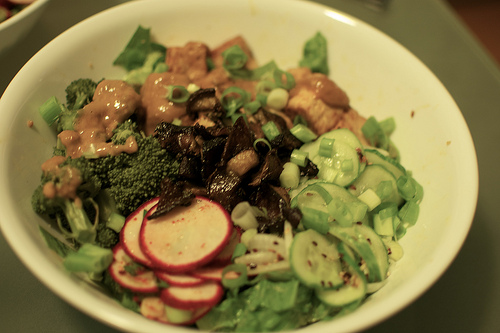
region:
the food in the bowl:
[30, 24, 423, 331]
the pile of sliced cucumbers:
[287, 129, 405, 306]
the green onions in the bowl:
[40, 24, 422, 331]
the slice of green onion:
[167, 84, 188, 104]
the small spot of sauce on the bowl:
[26, 119, 33, 128]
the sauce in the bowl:
[42, 37, 349, 208]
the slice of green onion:
[220, 264, 247, 285]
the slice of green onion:
[40, 97, 65, 127]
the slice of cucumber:
[289, 229, 345, 290]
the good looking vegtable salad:
[72, 88, 144, 149]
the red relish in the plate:
[127, 220, 237, 305]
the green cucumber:
[295, 185, 405, 265]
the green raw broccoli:
[90, 142, 176, 189]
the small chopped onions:
[265, 130, 360, 195]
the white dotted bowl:
[0, 61, 39, 205]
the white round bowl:
[6, 148, 474, 326]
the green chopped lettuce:
[231, 280, 338, 321]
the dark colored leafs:
[188, 95, 281, 197]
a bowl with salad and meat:
[5, 0, 487, 331]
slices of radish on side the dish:
[98, 198, 240, 317]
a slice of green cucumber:
[283, 225, 345, 290]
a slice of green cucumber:
[292, 176, 366, 225]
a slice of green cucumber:
[358, 142, 410, 177]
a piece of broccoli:
[100, 127, 185, 217]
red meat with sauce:
[80, 58, 258, 134]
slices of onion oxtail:
[290, 118, 340, 169]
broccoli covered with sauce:
[24, 145, 96, 249]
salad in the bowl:
[38, 64, 404, 323]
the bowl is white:
[363, 67, 393, 98]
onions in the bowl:
[115, 192, 217, 277]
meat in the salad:
[138, 81, 174, 123]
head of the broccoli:
[102, 156, 177, 203]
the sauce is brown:
[152, 87, 168, 114]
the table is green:
[420, 43, 476, 73]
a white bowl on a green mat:
[0, 0, 478, 330]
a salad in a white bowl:
[33, 23, 424, 332]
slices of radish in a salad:
[111, 192, 234, 322]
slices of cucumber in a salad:
[288, 130, 406, 305]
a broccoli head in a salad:
[84, 122, 174, 207]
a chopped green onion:
[223, 48, 246, 70]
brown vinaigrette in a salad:
[44, 39, 351, 202]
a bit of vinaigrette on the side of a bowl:
[26, 120, 36, 130]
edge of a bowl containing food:
[0, 0, 43, 51]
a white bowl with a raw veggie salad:
[0, 0, 481, 331]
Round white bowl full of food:
[1, 0, 480, 331]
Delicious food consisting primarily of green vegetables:
[30, 24, 425, 331]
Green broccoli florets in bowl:
[30, 75, 178, 244]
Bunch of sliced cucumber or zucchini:
[288, 126, 411, 307]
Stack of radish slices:
[113, 195, 247, 307]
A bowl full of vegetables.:
[0, 10, 478, 332]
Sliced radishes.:
[108, 193, 241, 310]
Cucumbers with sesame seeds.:
[291, 130, 416, 307]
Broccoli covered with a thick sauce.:
[30, 42, 301, 236]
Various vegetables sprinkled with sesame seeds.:
[22, 12, 425, 327]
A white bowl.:
[4, 10, 477, 332]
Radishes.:
[108, 193, 243, 310]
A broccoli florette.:
[30, 160, 101, 242]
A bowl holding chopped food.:
[2, 2, 482, 332]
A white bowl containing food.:
[1, 3, 489, 332]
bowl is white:
[0, 0, 481, 331]